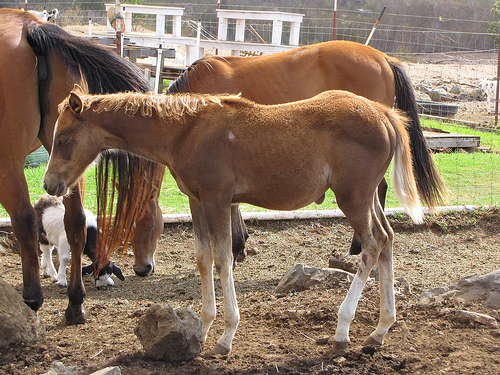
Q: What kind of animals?
A: Horse.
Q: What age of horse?
A: Young.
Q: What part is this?
A: Tail.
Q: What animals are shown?
A: Horses.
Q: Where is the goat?
A: Under the horses.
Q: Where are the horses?
A: Next to a pasture.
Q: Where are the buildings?
A: Behind the pasture.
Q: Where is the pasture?
A: Behind the fence.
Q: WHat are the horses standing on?
A: The dirt.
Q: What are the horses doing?
A: Eating.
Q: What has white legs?
A: The horse.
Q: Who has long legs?
A: The horse.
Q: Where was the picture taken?
A: A farm.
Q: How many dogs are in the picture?
A: One.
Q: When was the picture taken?
A: During the day.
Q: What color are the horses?
A: Tan.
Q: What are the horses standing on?
A: Dirt.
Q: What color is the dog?
A: Black and white.